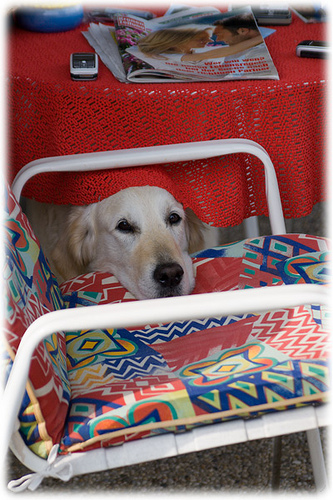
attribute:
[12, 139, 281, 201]
arm — white, metal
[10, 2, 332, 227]
table cloth — red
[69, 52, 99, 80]
phone — white, black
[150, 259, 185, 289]
nose — black 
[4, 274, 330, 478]
arm — white, metal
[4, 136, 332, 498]
lawn seat — designed